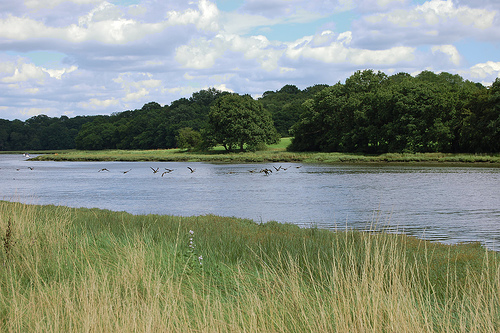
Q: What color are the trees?
A: Green.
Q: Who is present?
A: Nobody.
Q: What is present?
A: Birds.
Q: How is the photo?
A: Clear.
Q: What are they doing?
A: Flying.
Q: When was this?
A: Daytime.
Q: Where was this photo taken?
A: At a lake.